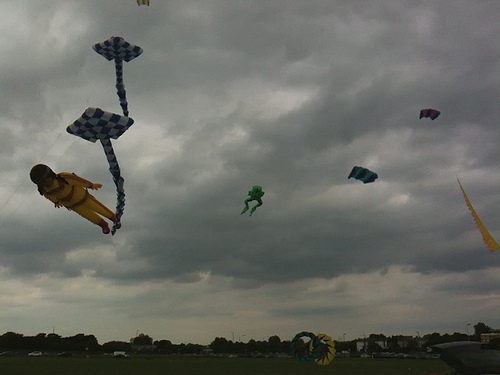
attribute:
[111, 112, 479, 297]
clouds — white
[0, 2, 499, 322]
sky — blue, cloudy, soggy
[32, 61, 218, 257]
kite — blue, yellow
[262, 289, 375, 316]
cloud — white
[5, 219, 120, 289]
cloud — white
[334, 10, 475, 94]
cloud — white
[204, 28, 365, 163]
cloud — white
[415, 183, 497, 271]
cloud — white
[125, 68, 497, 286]
cloud — white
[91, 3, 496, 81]
cloud — white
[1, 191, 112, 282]
cloud — white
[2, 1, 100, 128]
cloud — white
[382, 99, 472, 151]
kite — blue, red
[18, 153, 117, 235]
person kite — red, yellow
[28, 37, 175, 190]
kites — black, white, checkered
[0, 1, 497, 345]
clouds — heavy, white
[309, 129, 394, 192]
kite — blue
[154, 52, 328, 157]
clouds — white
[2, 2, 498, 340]
cloudy sky — soggy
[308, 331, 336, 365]
circle — yellow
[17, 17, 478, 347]
cloudy sky — soggy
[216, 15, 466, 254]
sky — grey, white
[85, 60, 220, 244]
kite — blue, white, checkered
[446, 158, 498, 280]
kite — yellow, long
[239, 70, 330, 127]
cloud — white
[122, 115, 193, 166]
cloud — white